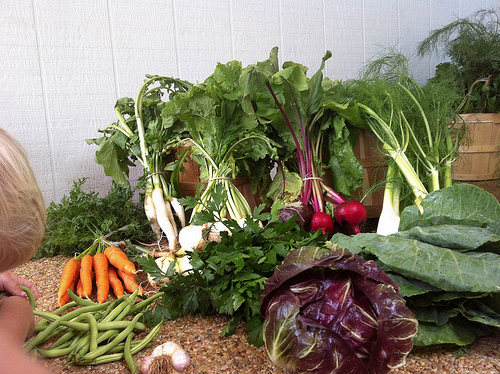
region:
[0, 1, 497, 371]
green vegetables on a table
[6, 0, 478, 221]
a white wall in front of vegetables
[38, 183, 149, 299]
orange carrots with leaves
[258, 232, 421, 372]
a purple lettuce over a table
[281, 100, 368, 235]
a bunch of radishes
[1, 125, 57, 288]
blonde hair on head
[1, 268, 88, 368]
a hand holding green beans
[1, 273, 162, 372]
green beans in front a person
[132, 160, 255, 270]
bunches of white vegetables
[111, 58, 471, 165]
green leaves of tubers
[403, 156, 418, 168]
part of a vegetable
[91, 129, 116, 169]
part of a wall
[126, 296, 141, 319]
part of a carrot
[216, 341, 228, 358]
part of the floor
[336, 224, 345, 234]
part of a vegetable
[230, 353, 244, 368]
part of a table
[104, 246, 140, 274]
An orange carrot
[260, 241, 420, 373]
A purple head of cabbage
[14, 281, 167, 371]
A pile of green beans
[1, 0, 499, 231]
A white wall behind vegetables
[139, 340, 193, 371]
A clove of garlic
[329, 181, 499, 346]
A green head of lettuce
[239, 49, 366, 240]
Red beets with leaves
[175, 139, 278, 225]
A wooden basket holding vegetables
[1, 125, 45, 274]
blond hair of child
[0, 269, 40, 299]
hand of a child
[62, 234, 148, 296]
carrots in front of green beans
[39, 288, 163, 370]
green beans next to carrots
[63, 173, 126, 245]
green on top of carrots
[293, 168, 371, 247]
radishes are next to lettuce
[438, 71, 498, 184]
barrel on side of greens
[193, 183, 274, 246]
onions are next o radishes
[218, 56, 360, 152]
green tops on radishes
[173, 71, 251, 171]
green tops on the onions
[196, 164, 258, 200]
rubber band around the group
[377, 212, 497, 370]
large leaves in front of radishes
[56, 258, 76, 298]
an orange carrot root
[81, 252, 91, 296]
an orange carrot root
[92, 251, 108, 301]
an orange carrot root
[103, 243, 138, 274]
an orange carrot root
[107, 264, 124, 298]
an orange carrot root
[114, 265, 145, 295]
an orange carrot root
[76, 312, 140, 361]
a green pea pod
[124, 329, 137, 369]
a green pea pod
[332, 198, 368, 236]
a bright red radish